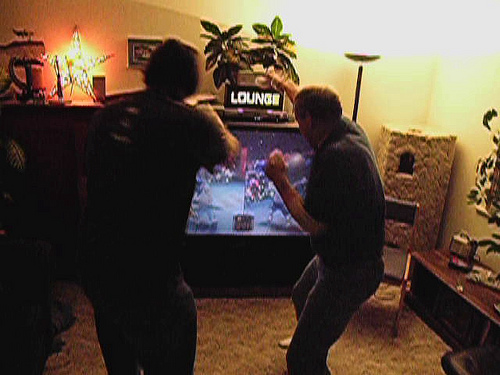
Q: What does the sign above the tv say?
A: Lounge.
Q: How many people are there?
A: Two.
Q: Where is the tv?
A: In front of the people.